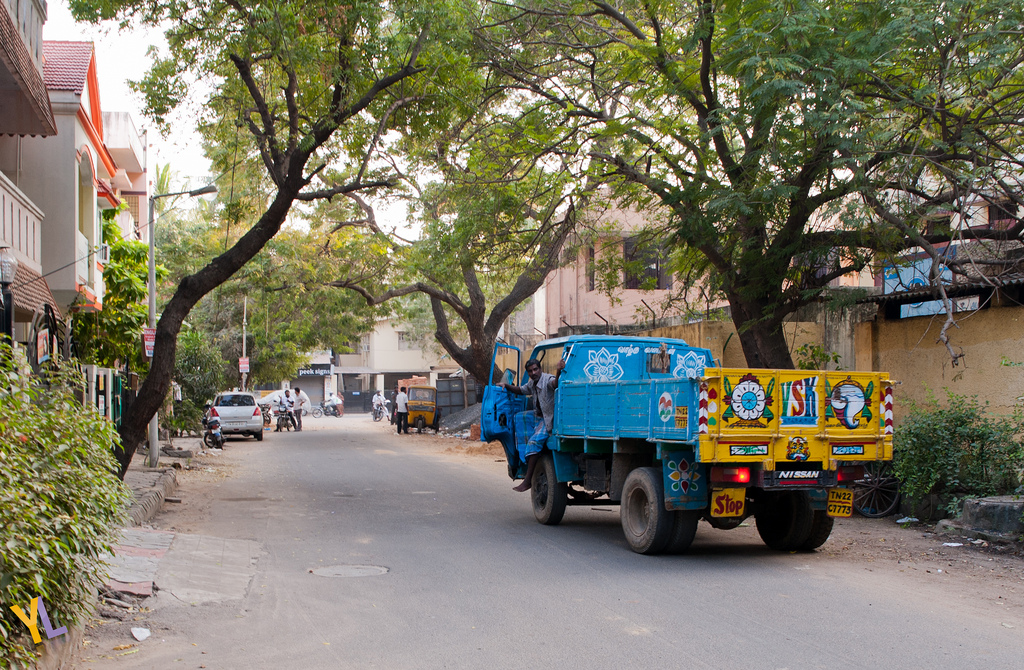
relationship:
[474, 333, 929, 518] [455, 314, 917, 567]
truck on street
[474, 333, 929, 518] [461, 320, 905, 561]
truck on roadway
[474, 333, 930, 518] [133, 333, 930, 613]
truck on street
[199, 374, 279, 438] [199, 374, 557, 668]
car on road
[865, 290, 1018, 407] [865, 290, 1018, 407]
wall on building